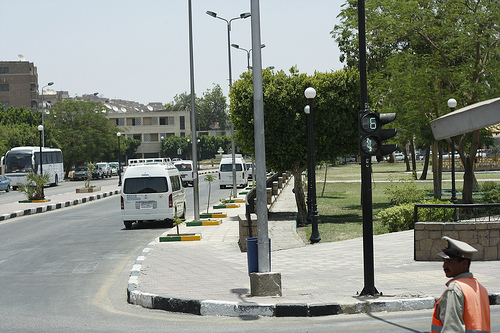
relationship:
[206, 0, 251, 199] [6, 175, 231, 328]
street lamp standing right of road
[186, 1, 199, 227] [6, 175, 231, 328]
street lamp standing right of road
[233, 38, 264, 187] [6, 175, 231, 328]
street lamp standing right of road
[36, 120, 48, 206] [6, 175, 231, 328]
street lamp standing left of road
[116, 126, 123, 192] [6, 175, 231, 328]
street lamp standing left of road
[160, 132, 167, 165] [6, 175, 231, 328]
street lamp standing left of road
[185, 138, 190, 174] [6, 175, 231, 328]
street lamp standing left of road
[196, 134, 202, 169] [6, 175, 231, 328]
street lamp standing left of road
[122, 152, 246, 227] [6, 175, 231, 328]
vans are driving on road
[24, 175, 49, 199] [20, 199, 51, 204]
trees are standing inside planters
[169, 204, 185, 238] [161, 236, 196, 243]
trees are standing inside planters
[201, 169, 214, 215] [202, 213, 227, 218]
trees are standing inside planters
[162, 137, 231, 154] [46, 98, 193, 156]
bushes surround office building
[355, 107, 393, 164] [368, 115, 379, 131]
crosswalk light displaying number 6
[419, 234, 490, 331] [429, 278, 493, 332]
crossing guard wearing a vest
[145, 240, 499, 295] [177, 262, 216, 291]
sidewalk made of bricks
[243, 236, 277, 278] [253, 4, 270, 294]
trash bin behind a street lamp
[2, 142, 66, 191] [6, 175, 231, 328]
bus parked on road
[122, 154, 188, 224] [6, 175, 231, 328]
van traveling on road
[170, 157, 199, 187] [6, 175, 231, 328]
van traveling on road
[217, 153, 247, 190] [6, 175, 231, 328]
van traveling on road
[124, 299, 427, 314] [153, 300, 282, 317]
street curb has stripes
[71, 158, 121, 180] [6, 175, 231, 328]
cars parked left of road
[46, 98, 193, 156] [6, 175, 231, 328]
office building behind road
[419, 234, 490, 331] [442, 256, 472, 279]
crossing guard has a head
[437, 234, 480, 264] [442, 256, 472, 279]
hat on top of head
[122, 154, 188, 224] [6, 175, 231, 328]
van parked right of road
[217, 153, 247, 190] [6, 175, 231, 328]
van parked right of road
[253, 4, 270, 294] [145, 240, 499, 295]
street lamp on top of sidewalk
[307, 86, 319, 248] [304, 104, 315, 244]
street lamp in front of a street lamp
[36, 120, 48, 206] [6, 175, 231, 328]
street lamp to left of a road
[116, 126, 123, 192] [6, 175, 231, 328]
street lamp to left of a road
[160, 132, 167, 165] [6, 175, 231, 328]
street lamp to left of a road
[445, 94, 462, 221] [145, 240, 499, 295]
street lamp behind sidewalk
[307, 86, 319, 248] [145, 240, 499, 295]
street lamp behind a sidewalk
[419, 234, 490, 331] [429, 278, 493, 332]
crossing guard wears a vest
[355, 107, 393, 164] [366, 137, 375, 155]
crosswalk light displays an electric pedestrian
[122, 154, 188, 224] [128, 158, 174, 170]
van has a raised roof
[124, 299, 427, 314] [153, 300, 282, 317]
street curb painted in stripes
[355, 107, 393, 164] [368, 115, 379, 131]
crosswalk light has a number 6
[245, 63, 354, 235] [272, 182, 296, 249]
sapling tree on top of walkway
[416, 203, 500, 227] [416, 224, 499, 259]
rail on top of wall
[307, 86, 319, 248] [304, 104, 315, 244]
street lamp in front of street lamp